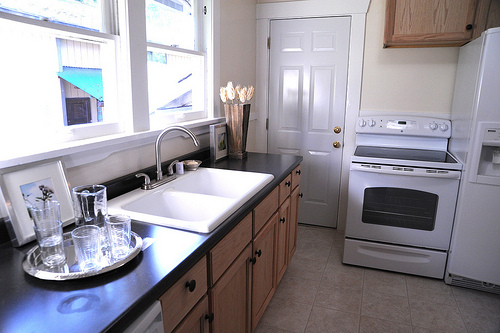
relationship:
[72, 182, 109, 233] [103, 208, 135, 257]
pitcher with glass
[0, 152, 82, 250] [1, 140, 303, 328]
photot on counter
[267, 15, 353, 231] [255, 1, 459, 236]
door on wall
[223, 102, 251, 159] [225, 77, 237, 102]
vase with flower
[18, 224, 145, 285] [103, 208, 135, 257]
tray with glass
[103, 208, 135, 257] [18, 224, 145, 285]
glass on tray